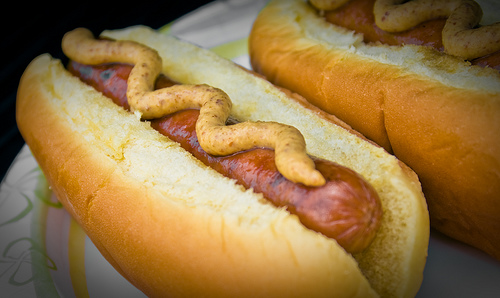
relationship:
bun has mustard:
[16, 25, 431, 297] [61, 25, 328, 187]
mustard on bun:
[61, 25, 328, 187] [16, 25, 431, 297]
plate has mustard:
[3, 2, 497, 297] [61, 25, 328, 187]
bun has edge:
[248, 1, 498, 259] [275, 3, 499, 93]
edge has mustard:
[275, 3, 499, 93] [292, 3, 464, 71]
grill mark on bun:
[77, 63, 115, 82] [16, 25, 431, 297]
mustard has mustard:
[61, 25, 328, 187] [61, 25, 328, 187]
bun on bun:
[16, 25, 431, 297] [16, 25, 431, 297]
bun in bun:
[16, 25, 431, 297] [16, 25, 431, 297]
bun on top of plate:
[16, 25, 431, 297] [3, 2, 497, 297]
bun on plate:
[16, 25, 431, 297] [3, 2, 497, 297]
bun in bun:
[248, 1, 498, 259] [16, 25, 431, 297]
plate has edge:
[3, 2, 497, 297] [0, 1, 214, 193]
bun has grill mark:
[16, 25, 431, 297] [77, 63, 115, 82]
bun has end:
[16, 25, 431, 297] [329, 170, 382, 251]